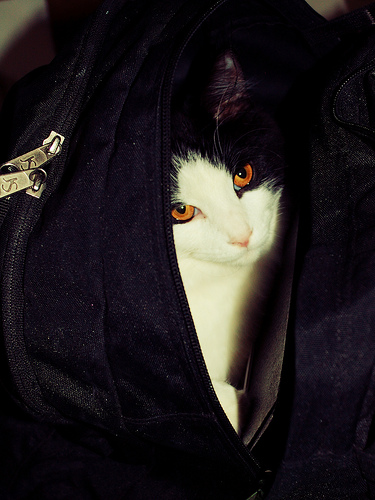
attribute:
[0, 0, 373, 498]
bag — big , black 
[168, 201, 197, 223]
eye — yellow 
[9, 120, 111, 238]
zipper — metal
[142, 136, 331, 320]
cat — white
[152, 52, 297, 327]
cat — white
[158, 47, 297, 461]
cat — white , black 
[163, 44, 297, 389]
cat — White 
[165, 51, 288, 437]
cat — white, black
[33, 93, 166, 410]
bag — big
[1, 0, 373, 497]
luggage — black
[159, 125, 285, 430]
cat — black, white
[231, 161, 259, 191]
eye — yellow 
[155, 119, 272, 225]
eyes — yellow-orange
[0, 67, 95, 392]
zipper — long, curved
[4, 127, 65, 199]
zipper — metal 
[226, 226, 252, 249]
nose — pink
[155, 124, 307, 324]
cat — white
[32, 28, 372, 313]
bag — black, big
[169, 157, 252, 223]
cat's eyes — orange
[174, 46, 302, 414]
cat — white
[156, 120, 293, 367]
cat — white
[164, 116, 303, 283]
cat — White 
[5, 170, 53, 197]
zipper — metal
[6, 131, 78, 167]
zipper — metal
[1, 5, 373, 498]
black bag — big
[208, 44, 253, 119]
cat ear — black 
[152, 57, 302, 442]
cat — white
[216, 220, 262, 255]
nose — pink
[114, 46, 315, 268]
cat — white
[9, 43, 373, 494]
bag —  black , big 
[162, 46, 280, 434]
cat — white